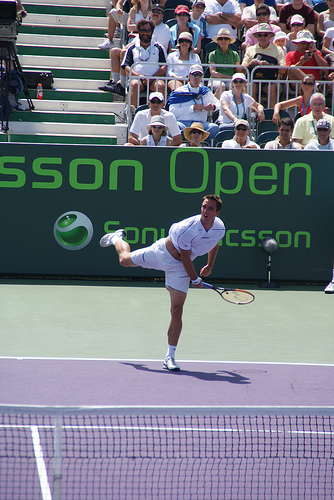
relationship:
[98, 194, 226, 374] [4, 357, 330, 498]
player on court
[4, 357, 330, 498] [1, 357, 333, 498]
court has lines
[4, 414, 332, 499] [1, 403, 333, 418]
mesh has tape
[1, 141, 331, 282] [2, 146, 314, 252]
wall has advertisements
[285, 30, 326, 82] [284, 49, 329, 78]
man has shirt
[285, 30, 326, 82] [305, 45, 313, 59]
man looking at phone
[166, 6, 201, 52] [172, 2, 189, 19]
woman has hat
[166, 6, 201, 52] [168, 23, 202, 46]
woman has sweater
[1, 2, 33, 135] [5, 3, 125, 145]
television camera on steps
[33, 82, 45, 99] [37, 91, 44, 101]
bottle has sports drink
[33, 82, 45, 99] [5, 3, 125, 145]
bottle on steps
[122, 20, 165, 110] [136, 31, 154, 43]
man has beard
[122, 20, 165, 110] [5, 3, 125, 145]
man sitting on aisle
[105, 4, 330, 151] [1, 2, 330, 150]
people are in stands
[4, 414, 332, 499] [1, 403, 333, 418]
mesh has edging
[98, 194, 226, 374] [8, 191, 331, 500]
player playing tennis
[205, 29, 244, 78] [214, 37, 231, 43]
person has glasses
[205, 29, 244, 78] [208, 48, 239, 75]
person has shirt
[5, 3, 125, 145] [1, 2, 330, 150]
steps are in bleachers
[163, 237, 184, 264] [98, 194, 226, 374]
belly visible on player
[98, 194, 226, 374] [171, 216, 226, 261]
player has shirt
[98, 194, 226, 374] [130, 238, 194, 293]
player has pants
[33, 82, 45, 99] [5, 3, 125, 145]
bottle on stairs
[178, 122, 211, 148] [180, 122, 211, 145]
woman has hat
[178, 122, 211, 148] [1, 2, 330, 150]
woman in stands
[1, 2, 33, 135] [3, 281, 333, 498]
television camera behind tennis court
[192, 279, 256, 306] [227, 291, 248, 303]
tennis racket has letter p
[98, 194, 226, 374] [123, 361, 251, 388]
player has shadow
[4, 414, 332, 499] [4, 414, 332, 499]
mesh has mesh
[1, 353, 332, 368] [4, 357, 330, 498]
foul line on court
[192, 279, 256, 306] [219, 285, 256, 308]
tennis racket has head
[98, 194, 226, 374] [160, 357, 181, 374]
player has foot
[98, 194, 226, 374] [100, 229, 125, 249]
player has foot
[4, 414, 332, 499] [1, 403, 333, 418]
mesh has top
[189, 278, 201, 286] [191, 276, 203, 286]
sweatband on wrist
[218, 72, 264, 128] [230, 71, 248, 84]
woman has hat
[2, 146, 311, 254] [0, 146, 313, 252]
tournament sign has green letters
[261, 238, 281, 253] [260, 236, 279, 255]
tennis ball in flight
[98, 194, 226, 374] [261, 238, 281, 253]
player returning tennis ball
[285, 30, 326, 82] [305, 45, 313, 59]
spectator on phone